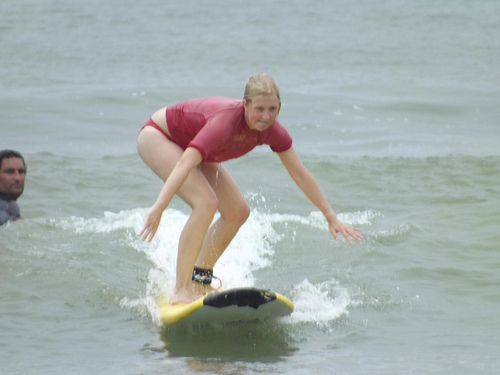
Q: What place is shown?
A: It is an ocean.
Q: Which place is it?
A: It is an ocean.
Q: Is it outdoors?
A: Yes, it is outdoors.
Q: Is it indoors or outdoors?
A: It is outdoors.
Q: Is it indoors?
A: No, it is outdoors.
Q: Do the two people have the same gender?
A: No, they are both male and female.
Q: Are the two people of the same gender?
A: No, they are both male and female.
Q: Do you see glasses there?
A: No, there are no glasses.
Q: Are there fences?
A: No, there are no fences.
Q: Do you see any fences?
A: No, there are no fences.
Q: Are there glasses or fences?
A: No, there are no fences or glasses.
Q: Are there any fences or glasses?
A: No, there are no fences or glasses.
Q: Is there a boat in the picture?
A: No, there are no boats.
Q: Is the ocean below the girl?
A: Yes, the ocean is below the girl.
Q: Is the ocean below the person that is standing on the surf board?
A: Yes, the ocean is below the girl.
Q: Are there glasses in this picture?
A: No, there are no glasses.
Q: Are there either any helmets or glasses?
A: No, there are no glasses or helmets.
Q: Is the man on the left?
A: Yes, the man is on the left of the image.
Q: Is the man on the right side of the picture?
A: No, the man is on the left of the image.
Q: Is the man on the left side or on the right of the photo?
A: The man is on the left of the image.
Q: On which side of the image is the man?
A: The man is on the left of the image.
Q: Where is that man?
A: The man is in the ocean.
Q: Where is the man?
A: The man is in the ocean.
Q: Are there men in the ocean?
A: Yes, there is a man in the ocean.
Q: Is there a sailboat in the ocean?
A: No, there is a man in the ocean.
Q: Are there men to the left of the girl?
A: Yes, there is a man to the left of the girl.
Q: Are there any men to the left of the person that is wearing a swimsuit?
A: Yes, there is a man to the left of the girl.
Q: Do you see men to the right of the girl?
A: No, the man is to the left of the girl.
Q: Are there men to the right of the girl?
A: No, the man is to the left of the girl.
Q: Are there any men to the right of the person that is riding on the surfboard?
A: No, the man is to the left of the girl.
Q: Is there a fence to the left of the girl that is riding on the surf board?
A: No, there is a man to the left of the girl.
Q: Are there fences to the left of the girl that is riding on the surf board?
A: No, there is a man to the left of the girl.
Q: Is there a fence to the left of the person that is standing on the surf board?
A: No, there is a man to the left of the girl.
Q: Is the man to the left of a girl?
A: Yes, the man is to the left of a girl.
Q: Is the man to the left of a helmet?
A: No, the man is to the left of a girl.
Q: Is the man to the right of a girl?
A: No, the man is to the left of a girl.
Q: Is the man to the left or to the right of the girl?
A: The man is to the left of the girl.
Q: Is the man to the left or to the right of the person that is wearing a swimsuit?
A: The man is to the left of the girl.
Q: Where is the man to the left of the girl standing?
A: The man is standing in the ocean.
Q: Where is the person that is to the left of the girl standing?
A: The man is standing in the ocean.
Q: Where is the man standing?
A: The man is standing in the ocean.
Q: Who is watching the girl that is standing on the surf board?
A: The man is watching the girl.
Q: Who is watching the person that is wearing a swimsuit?
A: The man is watching the girl.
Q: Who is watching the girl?
A: The man is watching the girl.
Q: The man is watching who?
A: The man is watching the girl.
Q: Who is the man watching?
A: The man is watching the girl.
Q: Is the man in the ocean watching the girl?
A: Yes, the man is watching the girl.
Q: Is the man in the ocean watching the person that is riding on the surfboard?
A: Yes, the man is watching the girl.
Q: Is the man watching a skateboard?
A: No, the man is watching the girl.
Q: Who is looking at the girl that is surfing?
A: The man is looking at the girl.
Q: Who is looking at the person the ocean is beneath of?
A: The man is looking at the girl.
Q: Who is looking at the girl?
A: The man is looking at the girl.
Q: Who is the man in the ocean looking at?
A: The man is looking at the girl.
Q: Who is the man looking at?
A: The man is looking at the girl.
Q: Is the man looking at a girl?
A: Yes, the man is looking at a girl.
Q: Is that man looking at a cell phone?
A: No, the man is looking at a girl.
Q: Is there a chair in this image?
A: No, there are no chairs.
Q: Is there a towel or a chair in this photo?
A: No, there are no chairs or towels.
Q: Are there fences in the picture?
A: No, there are no fences.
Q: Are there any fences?
A: No, there are no fences.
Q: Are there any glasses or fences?
A: No, there are no fences or glasses.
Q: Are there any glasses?
A: No, there are no glasses.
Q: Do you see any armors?
A: No, there are no armors.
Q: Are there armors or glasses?
A: No, there are no armors or glasses.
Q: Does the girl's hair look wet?
A: Yes, the hair is wet.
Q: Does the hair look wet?
A: Yes, the hair is wet.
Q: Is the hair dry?
A: No, the hair is wet.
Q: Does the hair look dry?
A: No, the hair is wet.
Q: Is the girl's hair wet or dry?
A: The hair is wet.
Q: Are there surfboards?
A: Yes, there is a surfboard.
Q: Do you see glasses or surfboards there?
A: Yes, there is a surfboard.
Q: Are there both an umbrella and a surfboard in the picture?
A: No, there is a surfboard but no umbrellas.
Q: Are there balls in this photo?
A: No, there are no balls.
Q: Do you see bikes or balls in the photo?
A: No, there are no balls or bikes.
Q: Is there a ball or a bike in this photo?
A: No, there are no balls or bikes.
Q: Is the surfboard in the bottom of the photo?
A: Yes, the surfboard is in the bottom of the image.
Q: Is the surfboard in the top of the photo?
A: No, the surfboard is in the bottom of the image.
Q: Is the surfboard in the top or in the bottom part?
A: The surfboard is in the bottom of the image.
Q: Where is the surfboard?
A: The surfboard is in the ocean.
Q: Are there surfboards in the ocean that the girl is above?
A: Yes, there is a surfboard in the ocean.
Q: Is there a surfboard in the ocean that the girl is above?
A: Yes, there is a surfboard in the ocean.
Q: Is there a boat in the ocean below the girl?
A: No, there is a surfboard in the ocean.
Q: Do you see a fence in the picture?
A: No, there are no fences.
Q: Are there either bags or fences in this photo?
A: No, there are no fences or bags.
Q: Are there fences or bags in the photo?
A: No, there are no fences or bags.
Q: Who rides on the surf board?
A: The girl rides on the surf board.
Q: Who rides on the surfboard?
A: The girl rides on the surf board.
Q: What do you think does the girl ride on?
A: The girl rides on the surfboard.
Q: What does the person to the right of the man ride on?
A: The girl rides on the surfboard.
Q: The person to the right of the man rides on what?
A: The girl rides on the surfboard.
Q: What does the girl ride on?
A: The girl rides on the surfboard.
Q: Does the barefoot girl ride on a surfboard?
A: Yes, the girl rides on a surfboard.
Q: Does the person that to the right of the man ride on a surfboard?
A: Yes, the girl rides on a surfboard.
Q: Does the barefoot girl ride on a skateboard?
A: No, the girl rides on a surfboard.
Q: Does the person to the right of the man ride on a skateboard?
A: No, the girl rides on a surfboard.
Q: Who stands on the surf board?
A: The girl stands on the surf board.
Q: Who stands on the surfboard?
A: The girl stands on the surf board.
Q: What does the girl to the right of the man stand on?
A: The girl stands on the surfboard.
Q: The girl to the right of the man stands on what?
A: The girl stands on the surfboard.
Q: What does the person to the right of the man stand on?
A: The girl stands on the surfboard.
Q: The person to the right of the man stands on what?
A: The girl stands on the surfboard.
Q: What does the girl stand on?
A: The girl stands on the surfboard.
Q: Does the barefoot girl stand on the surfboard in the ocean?
A: Yes, the girl stands on the surfboard.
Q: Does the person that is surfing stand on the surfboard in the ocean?
A: Yes, the girl stands on the surfboard.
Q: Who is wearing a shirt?
A: The girl is wearing a shirt.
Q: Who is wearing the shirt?
A: The girl is wearing a shirt.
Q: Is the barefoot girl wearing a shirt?
A: Yes, the girl is wearing a shirt.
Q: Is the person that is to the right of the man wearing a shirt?
A: Yes, the girl is wearing a shirt.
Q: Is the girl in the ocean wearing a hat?
A: No, the girl is wearing a shirt.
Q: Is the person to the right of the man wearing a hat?
A: No, the girl is wearing a shirt.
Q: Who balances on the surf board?
A: The girl balances on the surf board.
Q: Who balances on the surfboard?
A: The girl balances on the surf board.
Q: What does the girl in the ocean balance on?
A: The girl balances on the surfboard.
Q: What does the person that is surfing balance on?
A: The girl balances on the surfboard.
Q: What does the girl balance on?
A: The girl balances on the surfboard.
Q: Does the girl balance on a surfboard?
A: Yes, the girl balances on a surfboard.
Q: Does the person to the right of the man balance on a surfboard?
A: Yes, the girl balances on a surfboard.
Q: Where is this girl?
A: The girl is in the ocean.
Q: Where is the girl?
A: The girl is in the ocean.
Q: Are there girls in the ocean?
A: Yes, there is a girl in the ocean.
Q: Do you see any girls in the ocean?
A: Yes, there is a girl in the ocean.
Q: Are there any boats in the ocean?
A: No, there is a girl in the ocean.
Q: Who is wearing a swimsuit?
A: The girl is wearing a swimsuit.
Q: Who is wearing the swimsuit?
A: The girl is wearing a swimsuit.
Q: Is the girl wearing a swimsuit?
A: Yes, the girl is wearing a swimsuit.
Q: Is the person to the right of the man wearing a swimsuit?
A: Yes, the girl is wearing a swimsuit.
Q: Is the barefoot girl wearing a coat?
A: No, the girl is wearing a swimsuit.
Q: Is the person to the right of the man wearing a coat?
A: No, the girl is wearing a swimsuit.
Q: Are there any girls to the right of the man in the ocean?
A: Yes, there is a girl to the right of the man.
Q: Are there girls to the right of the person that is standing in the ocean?
A: Yes, there is a girl to the right of the man.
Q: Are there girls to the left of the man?
A: No, the girl is to the right of the man.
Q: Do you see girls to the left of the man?
A: No, the girl is to the right of the man.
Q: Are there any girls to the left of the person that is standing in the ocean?
A: No, the girl is to the right of the man.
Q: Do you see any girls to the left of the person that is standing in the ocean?
A: No, the girl is to the right of the man.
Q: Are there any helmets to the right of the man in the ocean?
A: No, there is a girl to the right of the man.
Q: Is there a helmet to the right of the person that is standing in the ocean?
A: No, there is a girl to the right of the man.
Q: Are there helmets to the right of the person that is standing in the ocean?
A: No, there is a girl to the right of the man.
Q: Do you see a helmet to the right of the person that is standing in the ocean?
A: No, there is a girl to the right of the man.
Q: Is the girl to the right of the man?
A: Yes, the girl is to the right of the man.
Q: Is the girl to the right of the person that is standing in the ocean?
A: Yes, the girl is to the right of the man.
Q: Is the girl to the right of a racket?
A: No, the girl is to the right of the man.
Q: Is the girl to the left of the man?
A: No, the girl is to the right of the man.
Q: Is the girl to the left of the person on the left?
A: No, the girl is to the right of the man.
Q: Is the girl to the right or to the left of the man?
A: The girl is to the right of the man.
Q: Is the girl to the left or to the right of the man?
A: The girl is to the right of the man.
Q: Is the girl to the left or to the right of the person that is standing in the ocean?
A: The girl is to the right of the man.